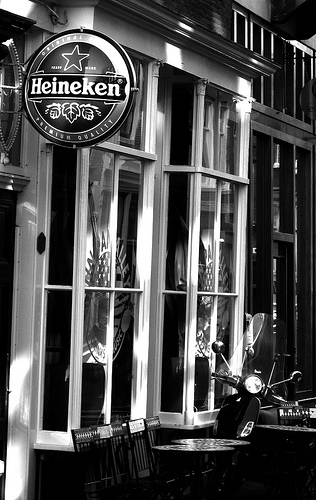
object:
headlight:
[244, 375, 262, 395]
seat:
[71, 422, 146, 498]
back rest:
[69, 418, 156, 494]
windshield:
[215, 313, 298, 392]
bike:
[206, 339, 314, 444]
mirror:
[211, 340, 227, 352]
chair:
[126, 418, 163, 496]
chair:
[68, 425, 106, 497]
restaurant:
[0, 0, 314, 498]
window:
[157, 64, 239, 415]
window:
[73, 50, 153, 446]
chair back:
[126, 419, 153, 483]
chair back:
[68, 424, 127, 495]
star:
[61, 43, 88, 73]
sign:
[21, 28, 137, 150]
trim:
[237, 98, 251, 182]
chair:
[124, 416, 159, 498]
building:
[1, 0, 314, 496]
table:
[149, 439, 252, 500]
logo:
[82, 232, 135, 365]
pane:
[82, 147, 142, 431]